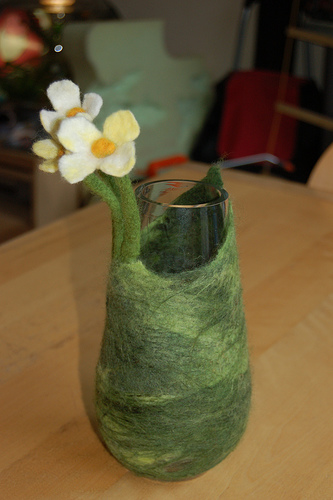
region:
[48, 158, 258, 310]
this is a flower made of felt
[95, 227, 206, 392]
the felt is green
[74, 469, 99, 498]
this is a table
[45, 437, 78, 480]
the table is light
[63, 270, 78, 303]
the table is empty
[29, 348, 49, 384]
there are no people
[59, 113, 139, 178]
White felt flower with orange center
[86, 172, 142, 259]
Green stems on felt flowers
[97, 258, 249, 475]
Felt bag around wine glass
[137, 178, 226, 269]
Wine glass with gold rim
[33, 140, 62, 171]
Yellowing white felt flower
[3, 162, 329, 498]
Tan wooden table in room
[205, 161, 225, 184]
Felt sticking over top of glass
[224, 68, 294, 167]
Red cloth behind table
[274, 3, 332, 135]
Shelf on far side of table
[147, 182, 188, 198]
Reflection in side of glass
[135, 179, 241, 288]
top of clear drinking glass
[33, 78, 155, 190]
small felt flower buds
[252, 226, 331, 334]
surface of brown table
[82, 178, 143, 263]
green felt flower stems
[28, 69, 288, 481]
green felt covered glass sitting on brown table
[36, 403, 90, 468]
wood grain in top of table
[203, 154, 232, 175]
piece of green felt on glass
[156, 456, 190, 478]
small stain on green felt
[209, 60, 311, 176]
piece of red clothing in background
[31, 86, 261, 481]
the vase on the table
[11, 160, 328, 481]
the table is wooden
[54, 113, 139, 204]
the flowers beside the vase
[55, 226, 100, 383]
the shadow on the table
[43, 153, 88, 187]
petal of the flower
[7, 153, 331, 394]
wood table under flower jar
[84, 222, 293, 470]
green cover on flower jar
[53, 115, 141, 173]
white cotton flowers on case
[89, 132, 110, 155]
yellow center of white flower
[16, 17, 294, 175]
blurry objects in room in background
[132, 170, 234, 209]
rim of flower jar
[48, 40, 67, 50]
object floating in air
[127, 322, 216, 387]
green fabric spooled together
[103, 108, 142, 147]
yellow stain on white flower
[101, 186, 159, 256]
green stem of flower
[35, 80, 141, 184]
fake white flowers on green stem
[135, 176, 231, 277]
glass cup cover with green fake stem of flower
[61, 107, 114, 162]
fake yellow pistils on white flowers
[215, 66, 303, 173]
red towel hanging in the background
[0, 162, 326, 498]
square wooden table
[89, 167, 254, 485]
green stamen around cup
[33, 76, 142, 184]
white fake petals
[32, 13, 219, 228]
white wall in the background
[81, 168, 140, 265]
thin green stem of white flowers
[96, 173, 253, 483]
glass cover with fake stem on top of wooden table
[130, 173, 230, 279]
glass on a table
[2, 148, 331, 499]
table made of wood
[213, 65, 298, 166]
red towel on a chair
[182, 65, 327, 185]
black colored chair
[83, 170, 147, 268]
green stems of flowers